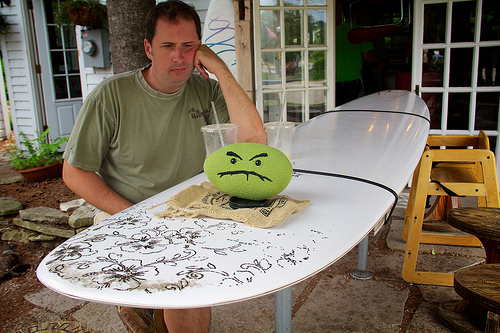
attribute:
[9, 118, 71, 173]
plant — hanging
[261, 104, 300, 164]
cup — plastic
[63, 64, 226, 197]
shirt — green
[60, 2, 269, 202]
male — adult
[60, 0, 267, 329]
man — disappointed, upset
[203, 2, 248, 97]
surfboard — white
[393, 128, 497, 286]
stool — childs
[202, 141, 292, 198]
nut — large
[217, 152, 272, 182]
face — drawn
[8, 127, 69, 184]
plant — potted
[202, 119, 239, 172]
cup — clear, plastic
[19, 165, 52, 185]
planter — red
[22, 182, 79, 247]
stones — stacked, landscaping stones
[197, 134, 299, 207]
stone — painted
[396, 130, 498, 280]
chair — high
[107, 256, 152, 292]
flower — black, hibiscus, tracing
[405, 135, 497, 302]
chair — wooden, high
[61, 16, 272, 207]
male — adult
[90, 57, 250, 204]
shirt — green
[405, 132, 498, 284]
stool — yellow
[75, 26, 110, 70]
meter — electricity meter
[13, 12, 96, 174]
door — open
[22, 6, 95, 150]
door — small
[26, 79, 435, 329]
surfboard — white, large, floral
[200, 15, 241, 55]
design — spiral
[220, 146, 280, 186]
face — angry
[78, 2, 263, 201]
male — adult